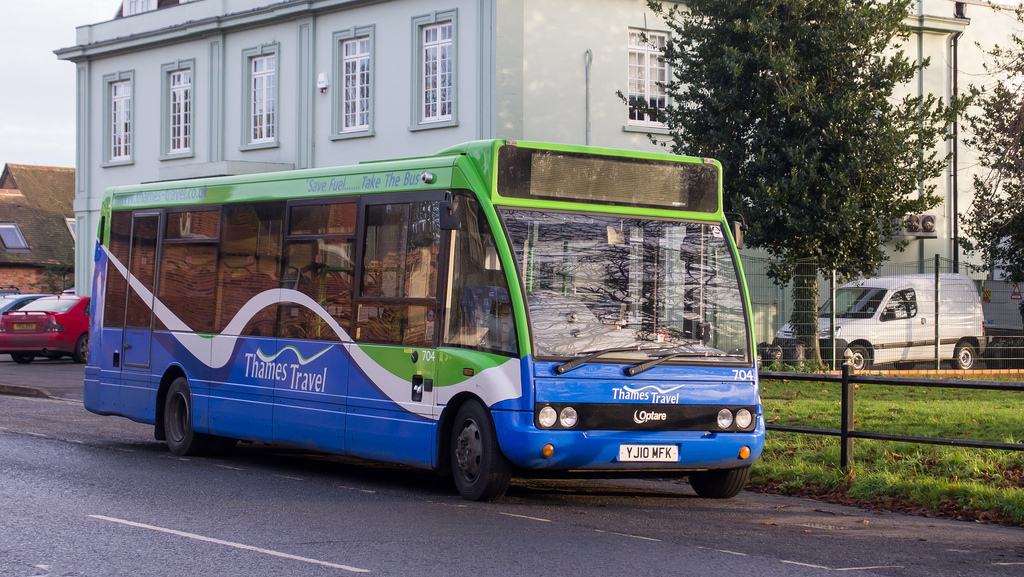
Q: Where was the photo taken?
A: On a city street.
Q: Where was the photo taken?
A: City street.